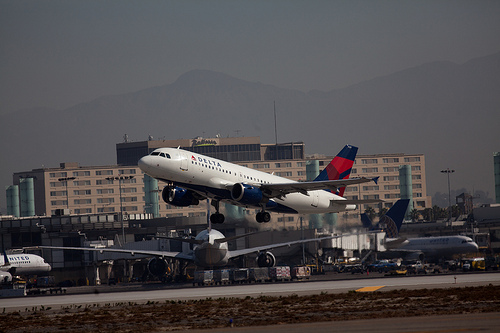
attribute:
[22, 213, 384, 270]
commercial airplane — large, silver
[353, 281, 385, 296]
stripe — yellow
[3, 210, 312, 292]
building — terminal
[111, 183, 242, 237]
engine — blue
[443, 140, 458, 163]
ground — gray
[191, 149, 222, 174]
brand — delta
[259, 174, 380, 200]
wing — red and blue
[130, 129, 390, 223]
plane — red, blue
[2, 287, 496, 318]
ground — part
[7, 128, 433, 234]
building — large, windowed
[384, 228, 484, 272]
plane — united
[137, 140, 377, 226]
plane — parked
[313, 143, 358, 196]
tail — red and blue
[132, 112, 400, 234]
airplane — white and blue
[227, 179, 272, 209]
engine — part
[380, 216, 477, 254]
airplane — white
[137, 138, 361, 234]
plane — delta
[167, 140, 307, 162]
tower — control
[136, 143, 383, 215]
plane — united airlines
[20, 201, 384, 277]
plane — united airlines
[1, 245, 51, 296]
plane — united airlines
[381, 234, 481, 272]
plane — united airlines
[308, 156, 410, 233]
tail — blue and red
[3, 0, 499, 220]
sky — dark and foggy